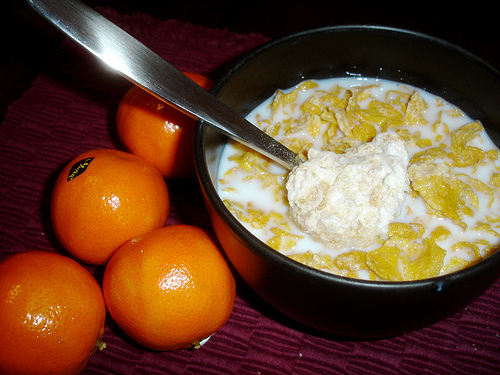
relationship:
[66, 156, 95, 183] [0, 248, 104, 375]
sticker on fruit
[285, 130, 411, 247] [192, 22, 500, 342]
sugar in bowl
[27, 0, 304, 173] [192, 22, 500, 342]
spoon in bowl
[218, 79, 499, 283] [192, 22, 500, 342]
corn flakes in bowl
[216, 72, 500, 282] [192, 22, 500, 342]
milk in bowl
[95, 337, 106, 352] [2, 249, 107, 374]
stem on fruit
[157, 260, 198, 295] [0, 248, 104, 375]
light on fruit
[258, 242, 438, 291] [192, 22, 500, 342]
light on bowl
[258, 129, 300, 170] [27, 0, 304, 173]
powder on spoon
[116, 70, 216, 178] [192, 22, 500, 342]
fruit next to bowl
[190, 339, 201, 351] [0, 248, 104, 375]
stem on fruit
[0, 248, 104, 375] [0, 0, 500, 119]
fruit on table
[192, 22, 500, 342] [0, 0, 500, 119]
bowl on table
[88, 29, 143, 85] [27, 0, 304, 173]
reflection on spoon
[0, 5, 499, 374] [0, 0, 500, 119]
mat on table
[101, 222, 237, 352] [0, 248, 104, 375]
peel of fruit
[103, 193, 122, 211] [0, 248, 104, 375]
light on fruit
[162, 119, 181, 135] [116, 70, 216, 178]
light on fruit